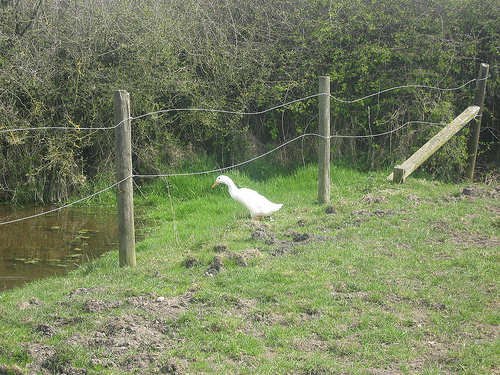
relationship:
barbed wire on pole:
[5, 72, 494, 231] [318, 75, 331, 203]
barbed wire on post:
[5, 72, 494, 231] [467, 55, 488, 176]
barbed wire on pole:
[5, 72, 494, 231] [393, 166, 407, 185]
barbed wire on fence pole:
[5, 72, 494, 231] [112, 88, 138, 266]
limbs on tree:
[73, 25, 151, 78] [49, 26, 261, 184]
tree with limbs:
[311, 7, 385, 98] [279, 3, 399, 168]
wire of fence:
[1, 124, 125, 132] [1, 68, 497, 328]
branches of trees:
[2, 5, 498, 165] [3, 10, 480, 223]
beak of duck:
[212, 181, 219, 186] [207, 169, 285, 224]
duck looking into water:
[210, 174, 283, 220] [0, 202, 117, 288]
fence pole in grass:
[112, 88, 138, 266] [4, 168, 489, 366]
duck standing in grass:
[190, 162, 284, 235] [3, 157, 499, 373]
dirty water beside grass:
[0, 194, 135, 294] [3, 157, 499, 373]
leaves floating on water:
[45, 223, 92, 267] [0, 202, 117, 288]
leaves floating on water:
[6, 224, 100, 268] [0, 202, 117, 288]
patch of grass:
[70, 213, 500, 375] [27, 205, 322, 373]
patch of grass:
[70, 213, 500, 375] [387, 180, 459, 278]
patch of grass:
[70, 213, 500, 375] [4, 168, 489, 366]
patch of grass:
[70, 213, 500, 375] [13, 267, 498, 372]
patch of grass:
[70, 213, 500, 375] [152, 166, 494, 259]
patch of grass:
[70, 213, 500, 375] [309, 202, 424, 329]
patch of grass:
[70, 213, 500, 375] [180, 314, 254, 359]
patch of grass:
[70, 213, 499, 372] [361, 301, 493, 373]